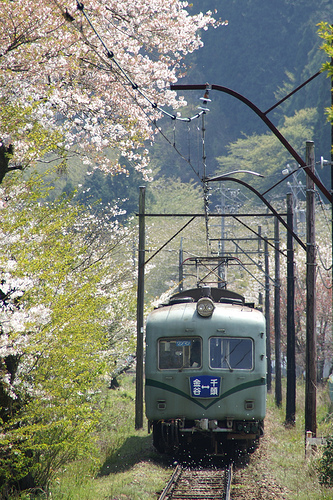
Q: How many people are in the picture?
A: None pictured.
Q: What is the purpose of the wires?
A: Provide the train with electricity.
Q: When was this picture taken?
A: Daytime.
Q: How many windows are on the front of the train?
A: Two.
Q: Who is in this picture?
A: No one.